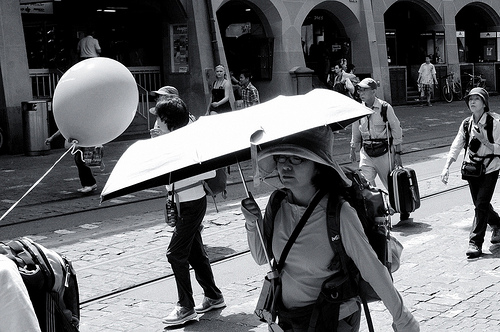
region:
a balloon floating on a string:
[0, 55, 141, 222]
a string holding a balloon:
[0, 139, 78, 219]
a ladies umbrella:
[102, 85, 373, 277]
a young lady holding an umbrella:
[101, 88, 426, 329]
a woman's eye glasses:
[275, 150, 308, 164]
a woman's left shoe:
[164, 306, 198, 324]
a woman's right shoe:
[198, 298, 225, 314]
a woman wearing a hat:
[442, 86, 499, 256]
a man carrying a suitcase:
[349, 78, 421, 228]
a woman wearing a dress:
[211, 65, 236, 110]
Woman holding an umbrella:
[98, 84, 380, 289]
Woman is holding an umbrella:
[106, 80, 380, 305]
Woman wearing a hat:
[255, 121, 357, 189]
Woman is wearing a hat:
[255, 122, 352, 182]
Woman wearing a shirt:
[230, 182, 430, 329]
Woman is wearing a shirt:
[238, 181, 425, 330]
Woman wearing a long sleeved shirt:
[238, 188, 424, 329]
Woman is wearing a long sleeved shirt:
[231, 181, 421, 330]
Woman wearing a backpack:
[254, 180, 401, 302]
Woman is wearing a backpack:
[262, 165, 404, 310]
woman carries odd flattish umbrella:
[97, 74, 437, 329]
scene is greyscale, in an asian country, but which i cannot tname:
[0, 1, 499, 330]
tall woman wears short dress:
[194, 59, 238, 120]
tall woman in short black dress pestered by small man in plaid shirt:
[198, 61, 264, 116]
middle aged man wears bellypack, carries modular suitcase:
[337, 69, 434, 243]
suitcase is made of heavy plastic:
[379, 162, 430, 221]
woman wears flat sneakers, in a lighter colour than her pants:
[132, 87, 237, 329]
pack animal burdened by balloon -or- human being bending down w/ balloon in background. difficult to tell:
[0, 44, 162, 329]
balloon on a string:
[0, 40, 152, 230]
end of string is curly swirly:
[73, 147, 91, 166]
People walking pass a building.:
[18, 47, 497, 219]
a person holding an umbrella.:
[90, 77, 398, 245]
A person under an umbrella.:
[106, 133, 377, 264]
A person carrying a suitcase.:
[383, 150, 433, 212]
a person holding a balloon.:
[1, 67, 133, 232]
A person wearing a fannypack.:
[361, 133, 399, 172]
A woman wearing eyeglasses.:
[262, 153, 313, 183]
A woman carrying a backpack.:
[305, 163, 405, 305]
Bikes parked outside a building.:
[441, 57, 486, 104]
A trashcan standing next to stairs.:
[23, 97, 52, 177]